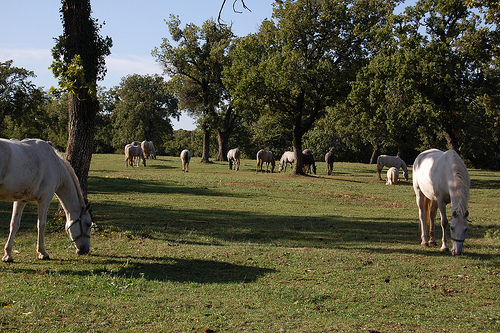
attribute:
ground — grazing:
[443, 112, 465, 153]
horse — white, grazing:
[124, 145, 148, 167]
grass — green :
[1, 155, 496, 332]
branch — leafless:
[214, 2, 226, 37]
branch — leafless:
[228, 2, 258, 15]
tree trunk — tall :
[57, 36, 105, 173]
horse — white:
[123, 142, 148, 168]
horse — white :
[406, 139, 474, 260]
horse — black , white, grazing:
[0, 132, 100, 263]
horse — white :
[410, 145, 474, 256]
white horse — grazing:
[402, 148, 477, 253]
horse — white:
[414, 148, 466, 254]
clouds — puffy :
[3, 44, 205, 126]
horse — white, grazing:
[276, 149, 294, 171]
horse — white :
[371, 143, 479, 247]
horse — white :
[360, 150, 406, 187]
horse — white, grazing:
[376, 153, 411, 181]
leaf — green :
[264, 60, 272, 72]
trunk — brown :
[50, 2, 120, 247]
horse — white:
[407, 142, 473, 251]